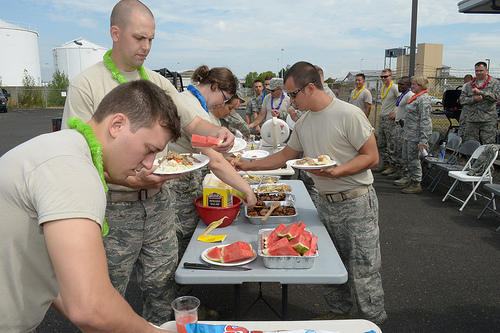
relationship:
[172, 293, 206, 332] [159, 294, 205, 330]
cup on table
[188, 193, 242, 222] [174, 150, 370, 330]
bowl on table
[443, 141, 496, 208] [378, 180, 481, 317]
chairs on pavement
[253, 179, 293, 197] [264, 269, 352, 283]
chips on table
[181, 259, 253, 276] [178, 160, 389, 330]
knife on table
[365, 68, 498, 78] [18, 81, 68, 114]
wire on fence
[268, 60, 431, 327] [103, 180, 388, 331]
man wearing pants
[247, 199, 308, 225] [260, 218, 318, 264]
tray has slices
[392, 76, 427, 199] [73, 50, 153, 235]
men wearing leis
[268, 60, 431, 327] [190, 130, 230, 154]
man holding slice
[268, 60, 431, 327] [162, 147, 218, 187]
man holding plate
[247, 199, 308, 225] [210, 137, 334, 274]
tray of food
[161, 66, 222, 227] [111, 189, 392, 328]
woman wearing fatigues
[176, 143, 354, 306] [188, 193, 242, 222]
table has bowl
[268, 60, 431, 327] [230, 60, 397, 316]
man wearing sunglasses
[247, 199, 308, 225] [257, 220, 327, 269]
tray of slices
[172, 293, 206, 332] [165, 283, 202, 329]
cup with juice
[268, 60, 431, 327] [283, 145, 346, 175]
man serving food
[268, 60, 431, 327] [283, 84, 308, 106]
man in shades